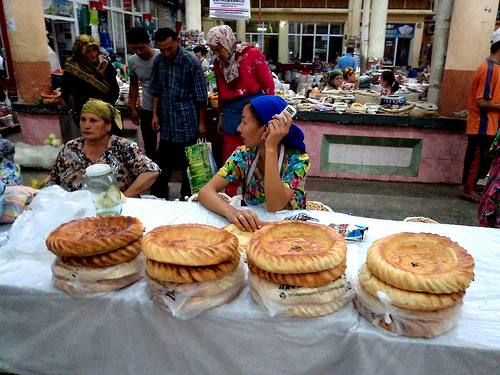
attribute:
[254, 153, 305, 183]
scarf — head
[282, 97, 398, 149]
foil packaging — blue , white 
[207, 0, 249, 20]
sign — white, hanging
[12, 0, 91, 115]
column — large, brown, tan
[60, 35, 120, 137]
woman — standing, watching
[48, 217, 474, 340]
bread — ethnic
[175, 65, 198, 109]
bag — green, white, plastic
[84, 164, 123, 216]
clear jar — large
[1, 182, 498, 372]
table cloth — white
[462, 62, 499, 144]
shirt — orange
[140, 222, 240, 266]
bread — ethnic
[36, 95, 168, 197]
woman — sitting, looking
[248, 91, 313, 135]
scarf — blue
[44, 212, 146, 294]
bread — ethnic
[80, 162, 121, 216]
jar — glass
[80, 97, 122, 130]
scarf — green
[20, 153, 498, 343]
cloth — white, table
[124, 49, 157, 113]
t-shirt — white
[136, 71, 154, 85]
stripe — black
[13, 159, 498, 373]
table cloth — white